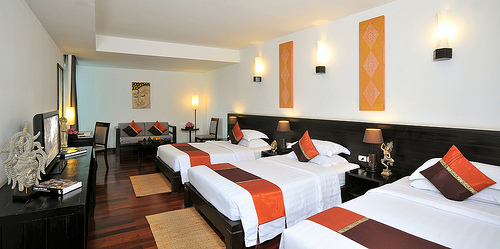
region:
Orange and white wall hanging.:
[345, 10, 397, 122]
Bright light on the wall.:
[421, 11, 459, 65]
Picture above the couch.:
[125, 77, 155, 111]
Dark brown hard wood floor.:
[104, 154, 121, 239]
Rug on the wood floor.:
[123, 158, 183, 208]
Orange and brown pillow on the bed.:
[418, 147, 498, 209]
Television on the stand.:
[26, 96, 70, 168]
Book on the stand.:
[29, 163, 84, 203]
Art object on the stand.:
[1, 110, 63, 206]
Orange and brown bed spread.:
[192, 158, 287, 225]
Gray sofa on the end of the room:
[110, 115, 180, 153]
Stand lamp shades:
[179, 80, 201, 142]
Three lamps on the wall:
[244, 7, 463, 99]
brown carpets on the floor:
[124, 165, 169, 200]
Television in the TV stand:
[28, 95, 73, 172]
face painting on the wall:
[127, 76, 156, 116]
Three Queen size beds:
[136, 105, 490, 244]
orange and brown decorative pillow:
[408, 127, 495, 217]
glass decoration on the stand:
[1, 120, 47, 203]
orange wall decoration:
[358, 20, 388, 117]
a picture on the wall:
[117, 72, 167, 115]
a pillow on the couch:
[125, 116, 142, 142]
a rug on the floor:
[125, 170, 173, 204]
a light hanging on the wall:
[306, 49, 334, 87]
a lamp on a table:
[360, 114, 386, 186]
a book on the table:
[24, 168, 83, 201]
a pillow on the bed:
[419, 132, 493, 224]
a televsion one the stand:
[25, 106, 75, 174]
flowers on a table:
[181, 116, 197, 137]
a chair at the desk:
[80, 112, 116, 164]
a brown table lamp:
[360, 123, 385, 173]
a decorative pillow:
[420, 141, 492, 201]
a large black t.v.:
[31, 110, 71, 175]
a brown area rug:
[127, 168, 173, 198]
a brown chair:
[90, 116, 114, 158]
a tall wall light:
[312, 31, 328, 76]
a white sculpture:
[2, 121, 52, 202]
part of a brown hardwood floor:
[90, 149, 173, 246]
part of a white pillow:
[310, 140, 350, 160]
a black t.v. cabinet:
[0, 146, 99, 245]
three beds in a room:
[153, 132, 475, 235]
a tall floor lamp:
[180, 85, 203, 150]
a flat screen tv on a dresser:
[31, 102, 71, 167]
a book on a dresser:
[34, 166, 85, 201]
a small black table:
[334, 146, 402, 203]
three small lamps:
[222, 114, 395, 170]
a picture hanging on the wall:
[126, 79, 156, 114]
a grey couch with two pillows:
[109, 112, 177, 156]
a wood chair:
[196, 114, 221, 146]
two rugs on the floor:
[131, 168, 185, 243]